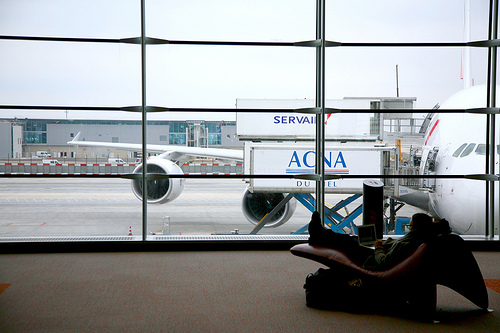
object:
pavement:
[0, 178, 424, 237]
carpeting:
[0, 251, 498, 292]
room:
[0, 2, 499, 331]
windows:
[145, 111, 319, 175]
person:
[307, 210, 432, 270]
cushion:
[290, 242, 425, 277]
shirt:
[374, 232, 418, 268]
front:
[433, 136, 499, 238]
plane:
[65, 5, 498, 243]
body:
[428, 84, 499, 238]